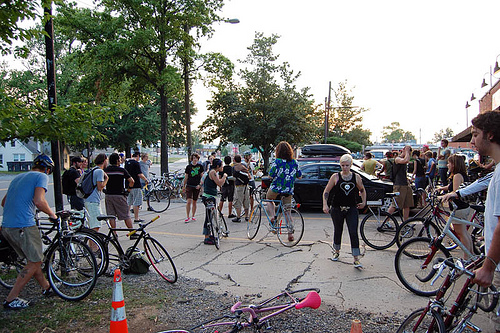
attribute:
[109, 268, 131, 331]
traffic cone — orange, silver, reflective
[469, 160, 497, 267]
shirt — white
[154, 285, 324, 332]
bicycle — pink framed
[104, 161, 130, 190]
shirt — black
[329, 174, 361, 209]
tank top — black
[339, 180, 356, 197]
heart — white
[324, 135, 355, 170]
hair — short, blonde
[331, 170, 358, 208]
tank top — black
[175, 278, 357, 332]
bicycle — pink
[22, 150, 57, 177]
helmet — blue